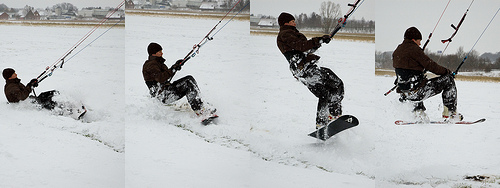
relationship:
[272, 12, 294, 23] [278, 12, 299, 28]
hat on head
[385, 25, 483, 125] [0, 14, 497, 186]
kite boarder in snow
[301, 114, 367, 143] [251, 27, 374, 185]
snowboard of ground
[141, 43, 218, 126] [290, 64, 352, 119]
man wearing ski pants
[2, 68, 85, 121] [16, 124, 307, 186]
man lying in snow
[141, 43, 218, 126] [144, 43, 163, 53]
man wearing cap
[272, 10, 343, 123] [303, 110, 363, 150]
man on snowboard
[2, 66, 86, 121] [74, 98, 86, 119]
man on snowboard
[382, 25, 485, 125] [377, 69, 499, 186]
kite boarder of ground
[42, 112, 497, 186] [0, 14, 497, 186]
tracks in snow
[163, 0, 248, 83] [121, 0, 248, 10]
wires reaching into sky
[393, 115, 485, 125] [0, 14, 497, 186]
snowboard in snow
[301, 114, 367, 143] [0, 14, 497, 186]
snowboard in snow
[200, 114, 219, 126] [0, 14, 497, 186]
snowboard in snow